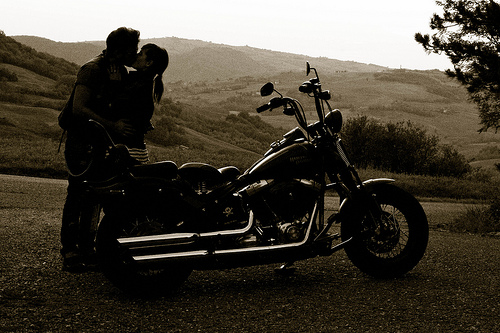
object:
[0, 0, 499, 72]
sky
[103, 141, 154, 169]
skirt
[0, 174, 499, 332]
ground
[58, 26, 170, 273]
they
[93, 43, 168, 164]
she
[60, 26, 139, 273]
he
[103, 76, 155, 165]
shirt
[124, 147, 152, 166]
tail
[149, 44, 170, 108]
pony tail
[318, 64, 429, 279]
motorcycle front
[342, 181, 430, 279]
front tire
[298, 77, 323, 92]
motorcycle handles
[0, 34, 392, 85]
mountain range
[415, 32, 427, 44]
tree leaves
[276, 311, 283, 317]
gravel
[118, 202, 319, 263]
two mufflers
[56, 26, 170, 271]
they kissing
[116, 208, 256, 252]
exhaust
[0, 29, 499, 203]
hills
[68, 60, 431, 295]
bike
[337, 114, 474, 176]
bush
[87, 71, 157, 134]
jacket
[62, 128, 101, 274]
wearing jeans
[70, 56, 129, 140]
black shirt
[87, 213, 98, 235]
chain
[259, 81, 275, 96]
mirrors on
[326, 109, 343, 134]
front headlight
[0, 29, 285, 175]
rolling hills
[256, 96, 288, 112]
handle bars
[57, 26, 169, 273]
couple embracing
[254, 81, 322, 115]
two handlebars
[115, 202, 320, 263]
two exhaust pipes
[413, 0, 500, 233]
shadowed tree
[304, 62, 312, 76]
front mirror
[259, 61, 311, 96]
two mirrors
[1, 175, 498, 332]
bare road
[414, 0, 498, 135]
thin tree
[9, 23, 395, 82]
large hill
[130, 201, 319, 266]
exhaust pipes